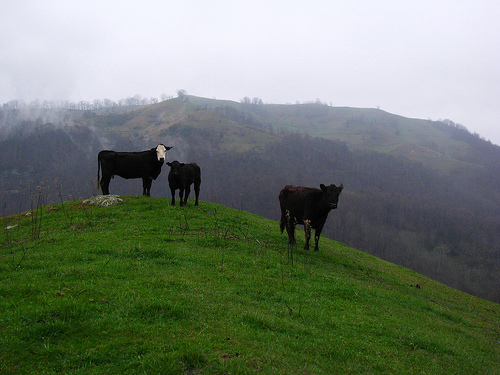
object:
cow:
[93, 142, 174, 198]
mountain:
[4, 195, 499, 372]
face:
[155, 144, 173, 164]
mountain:
[4, 94, 500, 308]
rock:
[82, 191, 126, 207]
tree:
[176, 89, 188, 97]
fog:
[0, 76, 119, 155]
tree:
[150, 96, 157, 106]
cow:
[164, 156, 211, 204]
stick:
[220, 227, 230, 271]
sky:
[0, 0, 500, 145]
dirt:
[214, 349, 245, 363]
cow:
[275, 179, 345, 250]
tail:
[279, 184, 291, 235]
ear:
[162, 143, 175, 152]